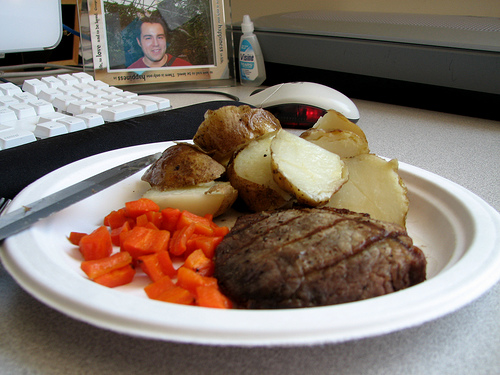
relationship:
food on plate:
[87, 102, 430, 302] [37, 130, 494, 362]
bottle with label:
[236, 13, 265, 86] [238, 37, 259, 83]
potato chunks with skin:
[232, 129, 359, 209] [155, 152, 217, 173]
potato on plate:
[139, 103, 410, 228] [2, 135, 499, 351]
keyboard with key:
[2, 66, 165, 160] [73, 108, 106, 128]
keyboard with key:
[2, 66, 165, 160] [59, 116, 86, 134]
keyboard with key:
[2, 66, 165, 160] [35, 118, 70, 141]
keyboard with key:
[2, 66, 165, 160] [42, 106, 69, 128]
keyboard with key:
[2, 66, 165, 160] [102, 104, 148, 124]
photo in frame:
[90, 20, 182, 67] [70, 4, 235, 94]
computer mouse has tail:
[224, 65, 367, 119] [134, 79, 242, 104]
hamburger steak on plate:
[220, 205, 413, 303] [404, 140, 491, 334]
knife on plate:
[6, 112, 235, 272] [2, 135, 499, 351]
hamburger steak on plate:
[205, 205, 429, 309] [3, 112, 498, 349]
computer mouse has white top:
[230, 78, 365, 125] [274, 81, 334, 103]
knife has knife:
[5, 150, 167, 241] [5, 150, 167, 241]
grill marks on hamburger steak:
[237, 218, 381, 253] [205, 205, 429, 309]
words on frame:
[106, 45, 178, 77] [86, 5, 113, 55]